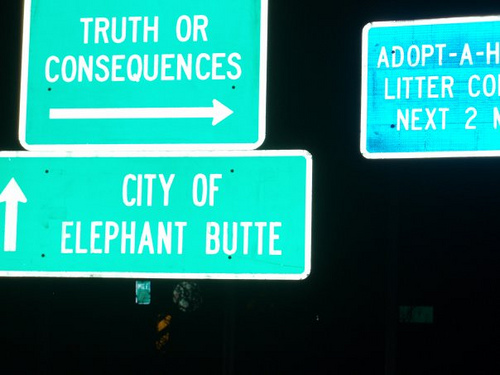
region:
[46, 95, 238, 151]
A white arrow on the sign.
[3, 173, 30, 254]
A white arrow pointing up.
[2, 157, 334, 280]
A green and white sign.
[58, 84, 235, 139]
The arrow is pointing to the right.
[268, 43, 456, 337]
It is dark outside.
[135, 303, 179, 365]
A black and yellow pole.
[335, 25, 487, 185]
A green sign posted.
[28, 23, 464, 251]
Three signs are showing.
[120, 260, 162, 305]
A small window on a building.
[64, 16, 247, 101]
The letters on the sign is white.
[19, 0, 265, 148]
green and white sign for Truth or Consequences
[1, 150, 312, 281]
green and white sign for the City of Elephant Butte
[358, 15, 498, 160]
green and white sign for Adopt-A-Highway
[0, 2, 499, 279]
collection of green and white signs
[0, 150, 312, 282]
sign advising City of Elephant Butte is straight ahead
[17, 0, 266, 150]
sign advising that Truth or Consequences is right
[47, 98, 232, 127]
white arrow point right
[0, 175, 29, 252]
white arrow point up on the sign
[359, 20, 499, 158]
Sign advising the next 2 miles is an adopted highway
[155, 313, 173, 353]
yellow and black striped sign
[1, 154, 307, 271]
A directional sign for the city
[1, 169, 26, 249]
An arrow on the sign pointing upwards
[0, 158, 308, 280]
A sign for the city of Elephant Butte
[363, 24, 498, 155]
An Adopt-A-Highway sign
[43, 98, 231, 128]
An arrow pointing to the right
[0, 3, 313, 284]
Directional signs on the road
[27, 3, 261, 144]
A sign pointing to Truth or Consequences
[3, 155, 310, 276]
A green sign on the road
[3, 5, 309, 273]
The signs point in a certain direction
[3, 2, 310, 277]
Traffic signs by the road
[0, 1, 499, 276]
the green street signs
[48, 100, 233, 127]
the long white arrow on the sign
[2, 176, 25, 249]
the white arrow on the sign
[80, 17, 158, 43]
the word TRUTH on the sign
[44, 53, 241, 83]
the word CONSEQUENCES on the sign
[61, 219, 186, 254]
the word ELEPHANT on the sign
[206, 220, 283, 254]
the word BUTTE on the sign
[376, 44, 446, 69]
the word ADOPT on the sign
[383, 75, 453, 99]
the word LITTER on the sign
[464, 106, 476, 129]
the number 2 on the sign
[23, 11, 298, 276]
road direction board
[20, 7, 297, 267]
green color board with white color text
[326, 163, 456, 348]
a dark place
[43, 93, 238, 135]
arrow mark symbol directed to right side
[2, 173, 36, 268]
straight arrow mark symbol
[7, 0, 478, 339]
three boards fixed in the place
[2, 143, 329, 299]
rectangle shape direction board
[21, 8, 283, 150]
square shape direction board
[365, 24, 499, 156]
board with green,white and blue color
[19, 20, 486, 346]
a dark background behind the boards